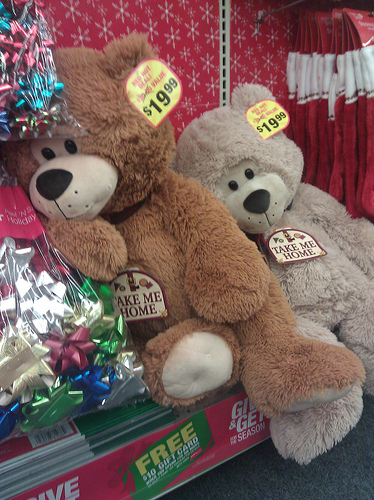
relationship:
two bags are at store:
[3, 28, 374, 452] [0, 4, 366, 492]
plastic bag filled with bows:
[3, 160, 149, 442] [12, 261, 108, 388]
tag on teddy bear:
[237, 95, 298, 146] [158, 74, 373, 463]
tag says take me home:
[237, 95, 298, 146] [251, 99, 273, 118]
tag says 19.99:
[237, 95, 298, 146] [253, 112, 293, 143]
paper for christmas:
[70, 3, 298, 107] [149, 6, 235, 47]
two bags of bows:
[3, 2, 160, 451] [12, 261, 108, 388]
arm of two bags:
[144, 173, 277, 327] [3, 28, 374, 452]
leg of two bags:
[211, 248, 362, 428] [3, 28, 374, 452]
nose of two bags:
[28, 163, 83, 208] [3, 28, 374, 452]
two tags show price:
[113, 52, 303, 157] [136, 71, 178, 121]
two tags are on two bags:
[113, 52, 303, 157] [3, 28, 374, 452]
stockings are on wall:
[276, 7, 372, 222] [2, 4, 361, 223]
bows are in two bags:
[12, 261, 108, 388] [3, 2, 160, 451]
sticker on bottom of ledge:
[124, 408, 222, 496] [14, 363, 297, 498]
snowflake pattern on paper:
[62, 4, 292, 91] [70, 3, 298, 107]